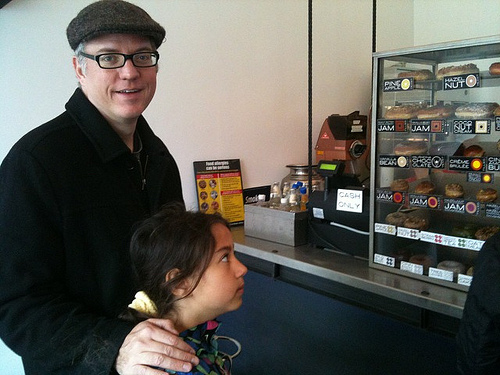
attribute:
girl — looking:
[128, 211, 246, 374]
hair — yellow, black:
[115, 212, 229, 327]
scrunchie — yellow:
[129, 292, 159, 316]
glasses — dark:
[79, 49, 159, 69]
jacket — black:
[1, 88, 187, 374]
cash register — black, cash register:
[295, 158, 369, 260]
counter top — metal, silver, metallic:
[225, 225, 467, 318]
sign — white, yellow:
[194, 160, 247, 226]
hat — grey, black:
[67, 3, 166, 51]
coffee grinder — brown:
[317, 113, 368, 175]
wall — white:
[1, 0, 500, 375]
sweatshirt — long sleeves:
[1, 91, 184, 374]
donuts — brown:
[446, 182, 465, 197]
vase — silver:
[284, 163, 324, 207]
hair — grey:
[74, 43, 85, 64]